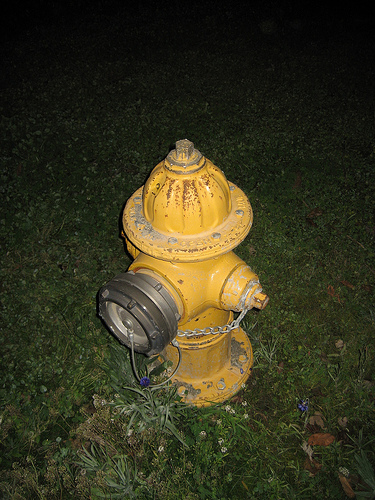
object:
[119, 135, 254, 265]
cover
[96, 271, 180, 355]
cover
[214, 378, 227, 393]
bolt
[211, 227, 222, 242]
bolt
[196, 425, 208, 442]
clover flowers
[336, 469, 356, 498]
leaves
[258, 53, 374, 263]
field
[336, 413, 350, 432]
leaves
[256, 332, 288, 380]
grass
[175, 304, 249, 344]
chain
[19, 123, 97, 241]
grass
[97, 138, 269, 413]
hydrant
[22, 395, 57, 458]
grass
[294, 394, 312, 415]
flowers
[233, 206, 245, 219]
bolts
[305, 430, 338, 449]
leaf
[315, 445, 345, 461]
grass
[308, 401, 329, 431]
leaves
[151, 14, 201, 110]
grass